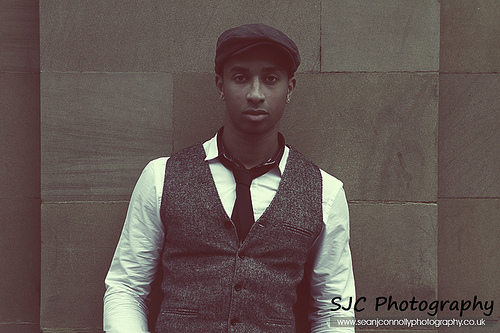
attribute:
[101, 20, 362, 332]
man — clean-shaven, standing, young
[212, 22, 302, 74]
hat — dark, black, paperboy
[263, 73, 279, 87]
eye — dark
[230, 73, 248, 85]
eye — dark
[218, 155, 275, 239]
tie — black, loosened, dark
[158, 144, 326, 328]
vest — gray, blue, tweed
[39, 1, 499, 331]
wall — grey, gray, brick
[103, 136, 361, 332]
shirt — white, dress, button-down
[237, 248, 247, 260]
button — black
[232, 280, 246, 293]
button — black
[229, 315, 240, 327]
button — black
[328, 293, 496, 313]
name — present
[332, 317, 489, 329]
website — present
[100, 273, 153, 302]
elbow — bent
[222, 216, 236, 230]
button — top, unbuttoned, open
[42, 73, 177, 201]
block — concrete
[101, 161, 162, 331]
sleeve — white, long